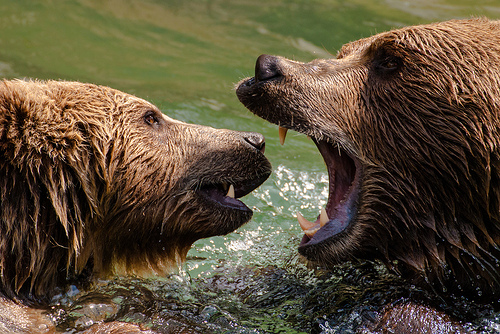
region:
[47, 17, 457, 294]
two bears face to face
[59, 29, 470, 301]
two bears with their mouths open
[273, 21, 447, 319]
a bear with its mouth wide open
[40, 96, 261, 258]
a bear with its mouth open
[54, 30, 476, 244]
two bears in the water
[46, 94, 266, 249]
a bear with brown eyes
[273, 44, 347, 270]
a bears long teeth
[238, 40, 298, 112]
a bears black nose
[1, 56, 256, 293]
a brown bear in the water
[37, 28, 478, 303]
two brown bears in the water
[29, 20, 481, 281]
two brown bears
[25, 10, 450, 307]
two brown bear playing in water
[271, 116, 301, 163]
large white teeth in bears mouth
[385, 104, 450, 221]
bear's wet fur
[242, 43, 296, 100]
bears black nose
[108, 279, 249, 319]
bubbles created on waters surface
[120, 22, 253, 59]
clam water behind bears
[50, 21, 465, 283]
two brown bears wrestling with each other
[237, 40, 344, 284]
bears mouth in wide open position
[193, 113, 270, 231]
bears mouth slightly open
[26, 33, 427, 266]
two bears fighting with each other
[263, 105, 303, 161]
tooth of the bear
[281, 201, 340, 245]
bottom teeth of the bear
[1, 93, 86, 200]
brown fur of the bear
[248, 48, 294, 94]
nose of the bear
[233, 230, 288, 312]
water under the bear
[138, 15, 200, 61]
water in the background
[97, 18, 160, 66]
still water next to bears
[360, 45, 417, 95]
eye of the bear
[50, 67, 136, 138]
light hitting the bear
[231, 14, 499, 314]
Large bear with it's mouth open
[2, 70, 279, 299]
brown bear with it's mouth mostly closed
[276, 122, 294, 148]
pointy yellow top teeth of bear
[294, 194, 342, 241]
pointy bottom teeth of bear with mouth open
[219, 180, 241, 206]
one pointy tooth on this bear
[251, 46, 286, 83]
black nose up high on bear with mouth open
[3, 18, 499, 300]
2 big brown bears in the water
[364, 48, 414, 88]
dark eye on wet brown bear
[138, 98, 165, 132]
light brown eye on wet brown bear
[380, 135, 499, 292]
wet brown fur on bear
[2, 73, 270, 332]
brown furry bear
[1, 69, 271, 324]
furry brown bear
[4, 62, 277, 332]
brown bear in water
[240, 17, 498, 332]
big brown bear in water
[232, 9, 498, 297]
bear's mouth is open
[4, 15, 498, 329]
two brown bears in water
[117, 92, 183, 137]
bear's eye is open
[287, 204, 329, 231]
teeth in bear's mouth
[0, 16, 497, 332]
Bear's playing in water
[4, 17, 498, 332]
bears swimming in water